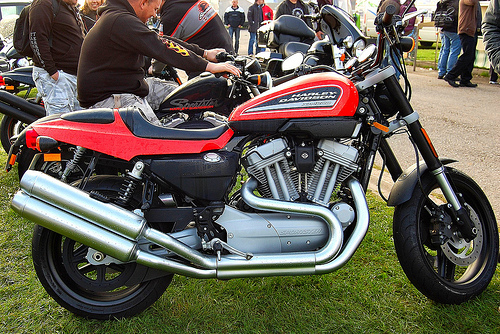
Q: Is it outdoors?
A: Yes, it is outdoors.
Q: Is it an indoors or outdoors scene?
A: It is outdoors.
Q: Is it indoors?
A: No, it is outdoors.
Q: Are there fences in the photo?
A: No, there are no fences.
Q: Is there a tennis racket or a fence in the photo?
A: No, there are no fences or rackets.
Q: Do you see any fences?
A: No, there are no fences.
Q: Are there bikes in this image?
A: Yes, there is a bike.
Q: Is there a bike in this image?
A: Yes, there is a bike.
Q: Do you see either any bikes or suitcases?
A: Yes, there is a bike.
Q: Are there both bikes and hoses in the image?
A: No, there is a bike but no hoses.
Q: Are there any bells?
A: No, there are no bells.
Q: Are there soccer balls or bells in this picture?
A: No, there are no bells or soccer balls.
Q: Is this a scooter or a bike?
A: This is a bike.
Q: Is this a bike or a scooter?
A: This is a bike.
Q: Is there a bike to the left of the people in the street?
A: Yes, there is a bike to the left of the people.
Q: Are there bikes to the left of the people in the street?
A: Yes, there is a bike to the left of the people.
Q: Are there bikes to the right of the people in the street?
A: No, the bike is to the left of the people.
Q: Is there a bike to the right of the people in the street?
A: No, the bike is to the left of the people.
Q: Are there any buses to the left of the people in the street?
A: No, there is a bike to the left of the people.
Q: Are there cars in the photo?
A: No, there are no cars.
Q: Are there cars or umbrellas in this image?
A: No, there are no cars or umbrellas.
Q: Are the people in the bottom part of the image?
A: No, the people are in the top of the image.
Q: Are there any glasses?
A: No, there are no glasses.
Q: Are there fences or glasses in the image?
A: No, there are no glasses or fences.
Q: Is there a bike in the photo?
A: Yes, there is a bike.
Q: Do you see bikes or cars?
A: Yes, there is a bike.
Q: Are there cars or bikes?
A: Yes, there is a bike.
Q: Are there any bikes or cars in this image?
A: Yes, there is a bike.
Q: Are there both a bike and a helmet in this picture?
A: No, there is a bike but no helmets.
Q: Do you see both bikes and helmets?
A: No, there is a bike but no helmets.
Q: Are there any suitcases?
A: No, there are no suitcases.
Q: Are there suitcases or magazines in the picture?
A: No, there are no suitcases or magazines.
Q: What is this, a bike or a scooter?
A: This is a bike.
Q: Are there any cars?
A: No, there are no cars.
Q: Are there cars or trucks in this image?
A: No, there are no cars or trucks.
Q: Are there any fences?
A: No, there are no fences.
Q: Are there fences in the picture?
A: No, there are no fences.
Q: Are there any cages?
A: No, there are no cages.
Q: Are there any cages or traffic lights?
A: No, there are no cages or traffic lights.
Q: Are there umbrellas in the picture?
A: No, there are no umbrellas.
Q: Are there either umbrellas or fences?
A: No, there are no umbrellas or fences.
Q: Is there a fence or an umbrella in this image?
A: No, there are no umbrellas or fences.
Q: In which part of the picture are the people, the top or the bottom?
A: The people are in the top of the image.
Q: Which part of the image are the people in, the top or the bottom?
A: The people are in the top of the image.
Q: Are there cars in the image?
A: No, there are no cars.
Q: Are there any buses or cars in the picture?
A: No, there are no cars or buses.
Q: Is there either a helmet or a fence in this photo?
A: No, there are no helmets or fences.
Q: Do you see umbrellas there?
A: No, there are no umbrellas.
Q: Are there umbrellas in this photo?
A: No, there are no umbrellas.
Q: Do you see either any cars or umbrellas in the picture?
A: No, there are no umbrellas or cars.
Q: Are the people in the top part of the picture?
A: Yes, the people are in the top of the image.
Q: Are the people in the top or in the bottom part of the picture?
A: The people are in the top of the image.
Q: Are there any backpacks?
A: Yes, there is a backpack.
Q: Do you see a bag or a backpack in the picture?
A: Yes, there is a backpack.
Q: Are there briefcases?
A: No, there are no briefcases.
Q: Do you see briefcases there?
A: No, there are no briefcases.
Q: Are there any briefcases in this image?
A: No, there are no briefcases.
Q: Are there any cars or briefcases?
A: No, there are no briefcases or cars.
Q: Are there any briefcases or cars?
A: No, there are no briefcases or cars.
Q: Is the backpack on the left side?
A: Yes, the backpack is on the left of the image.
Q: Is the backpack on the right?
A: No, the backpack is on the left of the image.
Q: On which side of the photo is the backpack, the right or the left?
A: The backpack is on the left of the image.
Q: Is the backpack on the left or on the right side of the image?
A: The backpack is on the left of the image.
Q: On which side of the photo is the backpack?
A: The backpack is on the left of the image.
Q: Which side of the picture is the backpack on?
A: The backpack is on the left of the image.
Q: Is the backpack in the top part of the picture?
A: Yes, the backpack is in the top of the image.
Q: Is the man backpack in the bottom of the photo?
A: No, the backpack is in the top of the image.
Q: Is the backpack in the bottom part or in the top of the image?
A: The backpack is in the top of the image.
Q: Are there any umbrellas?
A: No, there are no umbrellas.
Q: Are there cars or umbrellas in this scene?
A: No, there are no umbrellas or cars.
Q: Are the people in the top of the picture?
A: Yes, the people are in the top of the image.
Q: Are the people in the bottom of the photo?
A: No, the people are in the top of the image.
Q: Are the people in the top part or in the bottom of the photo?
A: The people are in the top of the image.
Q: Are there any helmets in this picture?
A: No, there are no helmets.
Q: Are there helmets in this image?
A: No, there are no helmets.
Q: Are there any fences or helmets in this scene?
A: No, there are no helmets or fences.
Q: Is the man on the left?
A: Yes, the man is on the left of the image.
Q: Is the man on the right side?
A: No, the man is on the left of the image.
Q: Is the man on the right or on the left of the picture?
A: The man is on the left of the image.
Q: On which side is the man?
A: The man is on the left of the image.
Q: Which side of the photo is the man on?
A: The man is on the left of the image.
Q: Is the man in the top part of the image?
A: Yes, the man is in the top of the image.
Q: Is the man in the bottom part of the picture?
A: No, the man is in the top of the image.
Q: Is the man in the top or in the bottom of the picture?
A: The man is in the top of the image.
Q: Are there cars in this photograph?
A: No, there are no cars.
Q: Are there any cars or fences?
A: No, there are no cars or fences.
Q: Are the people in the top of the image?
A: Yes, the people are in the top of the image.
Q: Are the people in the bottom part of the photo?
A: No, the people are in the top of the image.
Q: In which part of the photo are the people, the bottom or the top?
A: The people are in the top of the image.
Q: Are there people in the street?
A: Yes, there are people in the street.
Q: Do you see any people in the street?
A: Yes, there are people in the street.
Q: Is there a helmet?
A: No, there are no helmets.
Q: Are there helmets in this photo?
A: No, there are no helmets.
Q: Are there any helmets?
A: No, there are no helmets.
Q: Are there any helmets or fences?
A: No, there are no helmets or fences.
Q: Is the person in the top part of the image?
A: Yes, the person is in the top of the image.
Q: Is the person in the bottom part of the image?
A: No, the person is in the top of the image.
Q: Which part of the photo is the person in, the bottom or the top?
A: The person is in the top of the image.